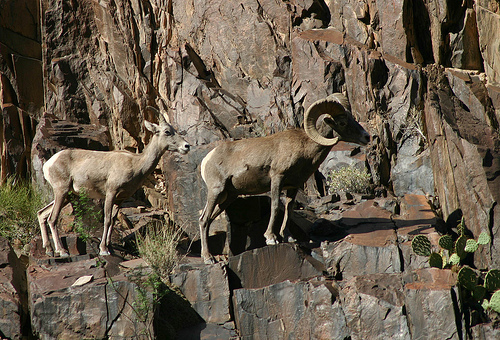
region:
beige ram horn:
[296, 90, 344, 150]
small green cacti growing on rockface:
[410, 211, 498, 317]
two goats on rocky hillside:
[30, 70, 420, 307]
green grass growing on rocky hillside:
[121, 220, 188, 275]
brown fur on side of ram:
[225, 140, 276, 170]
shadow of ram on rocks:
[310, 181, 435, 233]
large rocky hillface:
[35, 0, 490, 86]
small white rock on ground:
[61, 270, 91, 290]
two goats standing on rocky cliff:
[16, 72, 396, 294]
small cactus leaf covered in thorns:
[409, 234, 431, 261]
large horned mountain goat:
[177, 85, 383, 245]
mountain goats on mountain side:
[5, 55, 447, 330]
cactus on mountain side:
[405, 210, 485, 270]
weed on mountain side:
[125, 215, 175, 280]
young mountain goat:
[10, 100, 190, 260]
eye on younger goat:
[155, 125, 175, 140]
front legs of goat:
[95, 180, 115, 255]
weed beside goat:
[65, 190, 90, 251]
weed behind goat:
[0, 180, 40, 250]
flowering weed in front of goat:
[320, 165, 368, 206]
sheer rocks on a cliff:
[263, 255, 405, 335]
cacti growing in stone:
[410, 210, 496, 310]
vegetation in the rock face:
[120, 215, 190, 331]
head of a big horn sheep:
[297, 72, 378, 167]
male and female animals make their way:
[30, 62, 380, 268]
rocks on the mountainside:
[56, 0, 462, 95]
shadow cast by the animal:
[320, 205, 411, 237]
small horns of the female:
[136, 95, 191, 167]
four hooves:
[35, 237, 120, 257]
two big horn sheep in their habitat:
[30, 76, 401, 281]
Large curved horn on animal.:
[290, 109, 347, 162]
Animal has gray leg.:
[258, 182, 286, 224]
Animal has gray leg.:
[283, 197, 303, 247]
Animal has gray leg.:
[178, 194, 227, 263]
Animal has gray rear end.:
[200, 140, 252, 172]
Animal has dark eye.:
[333, 116, 351, 131]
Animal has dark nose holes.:
[354, 131, 381, 151]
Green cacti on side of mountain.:
[426, 217, 457, 259]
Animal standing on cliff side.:
[191, 165, 328, 287]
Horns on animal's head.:
[127, 92, 184, 126]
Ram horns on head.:
[293, 65, 380, 202]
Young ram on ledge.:
[30, 92, 192, 265]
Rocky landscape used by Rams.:
[153, 28, 430, 330]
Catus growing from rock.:
[390, 209, 438, 314]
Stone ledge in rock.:
[336, 194, 437, 295]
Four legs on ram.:
[41, 114, 155, 259]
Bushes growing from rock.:
[2, 157, 72, 243]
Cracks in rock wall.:
[85, 266, 135, 338]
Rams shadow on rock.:
[265, 155, 427, 267]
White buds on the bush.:
[329, 156, 373, 207]